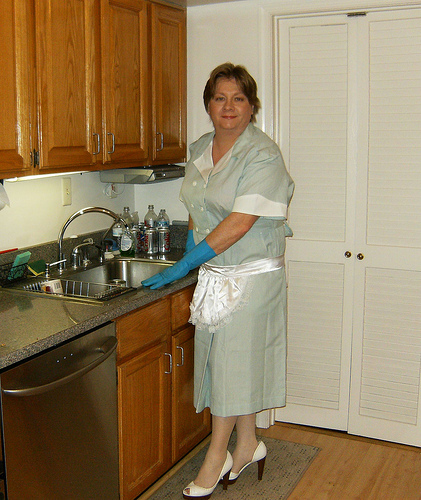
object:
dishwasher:
[0, 311, 126, 500]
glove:
[141, 238, 219, 287]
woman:
[141, 63, 293, 500]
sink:
[22, 257, 189, 296]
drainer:
[25, 276, 120, 300]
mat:
[138, 423, 324, 500]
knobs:
[356, 252, 364, 262]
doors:
[346, 0, 421, 452]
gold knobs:
[344, 250, 353, 260]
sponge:
[8, 251, 40, 278]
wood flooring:
[134, 411, 420, 500]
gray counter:
[0, 241, 197, 370]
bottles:
[156, 208, 171, 253]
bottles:
[143, 203, 160, 253]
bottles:
[118, 203, 134, 253]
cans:
[158, 227, 171, 254]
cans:
[144, 229, 158, 255]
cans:
[129, 229, 142, 253]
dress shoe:
[179, 447, 235, 498]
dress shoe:
[217, 440, 267, 485]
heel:
[222, 471, 230, 490]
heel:
[255, 456, 266, 481]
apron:
[185, 257, 286, 333]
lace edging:
[186, 298, 247, 336]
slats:
[288, 23, 347, 159]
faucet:
[55, 204, 137, 274]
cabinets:
[0, 0, 38, 174]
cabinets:
[112, 294, 180, 500]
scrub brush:
[104, 238, 121, 255]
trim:
[187, 275, 252, 332]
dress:
[176, 124, 294, 417]